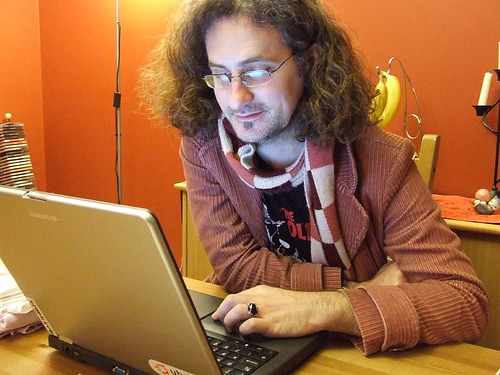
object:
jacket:
[177, 116, 490, 356]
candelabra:
[471, 70, 499, 196]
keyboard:
[203, 330, 281, 374]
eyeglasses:
[200, 52, 297, 90]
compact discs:
[1, 122, 24, 134]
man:
[159, 2, 492, 355]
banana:
[377, 69, 403, 128]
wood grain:
[1, 276, 497, 373]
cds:
[1, 160, 36, 166]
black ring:
[248, 301, 258, 319]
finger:
[223, 304, 254, 332]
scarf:
[210, 109, 354, 285]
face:
[205, 19, 299, 143]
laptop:
[0, 183, 336, 374]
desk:
[0, 230, 499, 375]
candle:
[477, 70, 493, 105]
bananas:
[368, 74, 388, 123]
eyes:
[247, 69, 267, 78]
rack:
[373, 53, 423, 160]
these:
[2, 110, 42, 180]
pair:
[197, 50, 298, 91]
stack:
[0, 120, 38, 194]